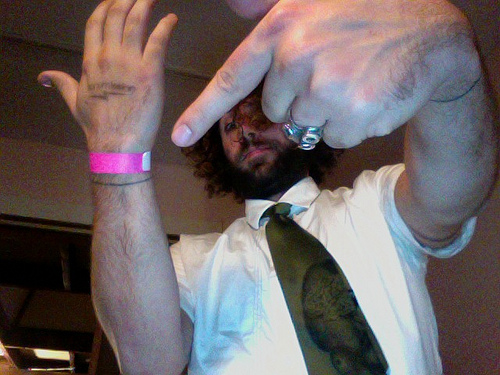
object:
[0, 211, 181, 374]
door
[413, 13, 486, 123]
hair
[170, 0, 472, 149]
hand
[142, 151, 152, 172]
white part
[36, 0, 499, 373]
man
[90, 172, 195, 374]
arm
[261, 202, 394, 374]
green tie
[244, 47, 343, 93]
ground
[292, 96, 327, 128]
finger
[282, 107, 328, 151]
ring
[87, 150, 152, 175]
pink wristband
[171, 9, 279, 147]
finger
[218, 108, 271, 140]
glasses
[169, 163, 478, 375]
white shirt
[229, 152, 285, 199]
beard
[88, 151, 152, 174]
bracelet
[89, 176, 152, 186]
line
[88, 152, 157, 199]
wrist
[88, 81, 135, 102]
tattoo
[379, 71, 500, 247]
arm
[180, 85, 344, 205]
hair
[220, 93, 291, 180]
face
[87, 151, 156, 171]
band